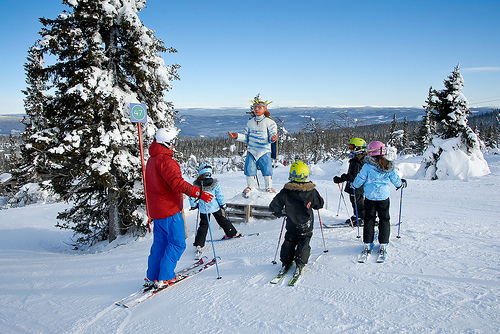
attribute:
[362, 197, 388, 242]
pants — black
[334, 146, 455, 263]
jacket — blue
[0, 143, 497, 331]
mound — snowy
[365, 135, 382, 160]
helmet — pink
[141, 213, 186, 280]
pants — blue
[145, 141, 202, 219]
coat — red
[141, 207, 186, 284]
pants — bright, blue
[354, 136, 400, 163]
helmet — pink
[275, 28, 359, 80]
blue sky — clear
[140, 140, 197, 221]
coat — red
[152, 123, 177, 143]
helmet — white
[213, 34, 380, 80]
sky — clear, blue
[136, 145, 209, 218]
jacket — red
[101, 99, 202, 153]
sign — blue, white, yellow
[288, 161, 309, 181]
helmet — yellow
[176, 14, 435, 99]
sky — clear, blue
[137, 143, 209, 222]
coat — red